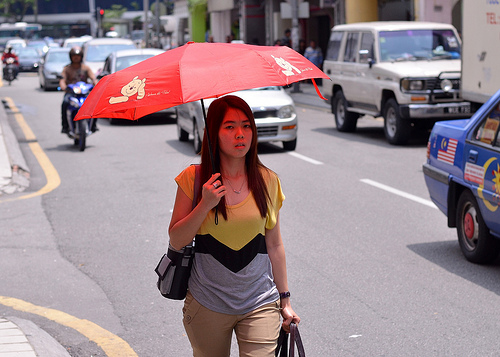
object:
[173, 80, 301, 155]
vehicle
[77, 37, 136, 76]
vehicle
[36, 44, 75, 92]
vehicle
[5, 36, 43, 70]
vehicle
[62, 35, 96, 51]
vehicle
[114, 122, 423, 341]
road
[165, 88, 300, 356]
woman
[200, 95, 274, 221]
hair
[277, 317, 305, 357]
holding straps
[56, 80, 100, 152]
blue motorcycle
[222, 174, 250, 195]
necklace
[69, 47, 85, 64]
helmet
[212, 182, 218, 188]
ring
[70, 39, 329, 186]
red umbrella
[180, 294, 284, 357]
brown pants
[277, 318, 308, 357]
handbag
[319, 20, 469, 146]
truck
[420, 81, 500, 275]
cab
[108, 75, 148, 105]
character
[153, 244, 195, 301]
bag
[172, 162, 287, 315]
blouse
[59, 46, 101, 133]
person